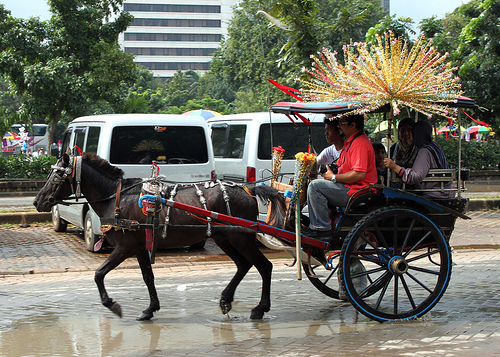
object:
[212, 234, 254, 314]
leg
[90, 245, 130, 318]
leg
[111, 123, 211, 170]
window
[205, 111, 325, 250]
vehicle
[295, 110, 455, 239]
people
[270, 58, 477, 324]
buggy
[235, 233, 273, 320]
leg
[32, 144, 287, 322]
horse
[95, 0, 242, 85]
building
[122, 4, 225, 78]
window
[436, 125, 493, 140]
umbrella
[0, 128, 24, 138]
umbrella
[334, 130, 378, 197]
shirt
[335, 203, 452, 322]
round wheel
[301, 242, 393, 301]
round wheel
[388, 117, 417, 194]
person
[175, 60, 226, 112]
trees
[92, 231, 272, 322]
legs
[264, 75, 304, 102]
streamer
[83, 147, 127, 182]
mane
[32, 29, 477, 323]
carriage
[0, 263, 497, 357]
water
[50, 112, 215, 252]
cars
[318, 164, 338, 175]
camera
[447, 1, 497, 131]
tree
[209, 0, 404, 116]
tree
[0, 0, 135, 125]
tree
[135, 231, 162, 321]
leg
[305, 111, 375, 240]
man